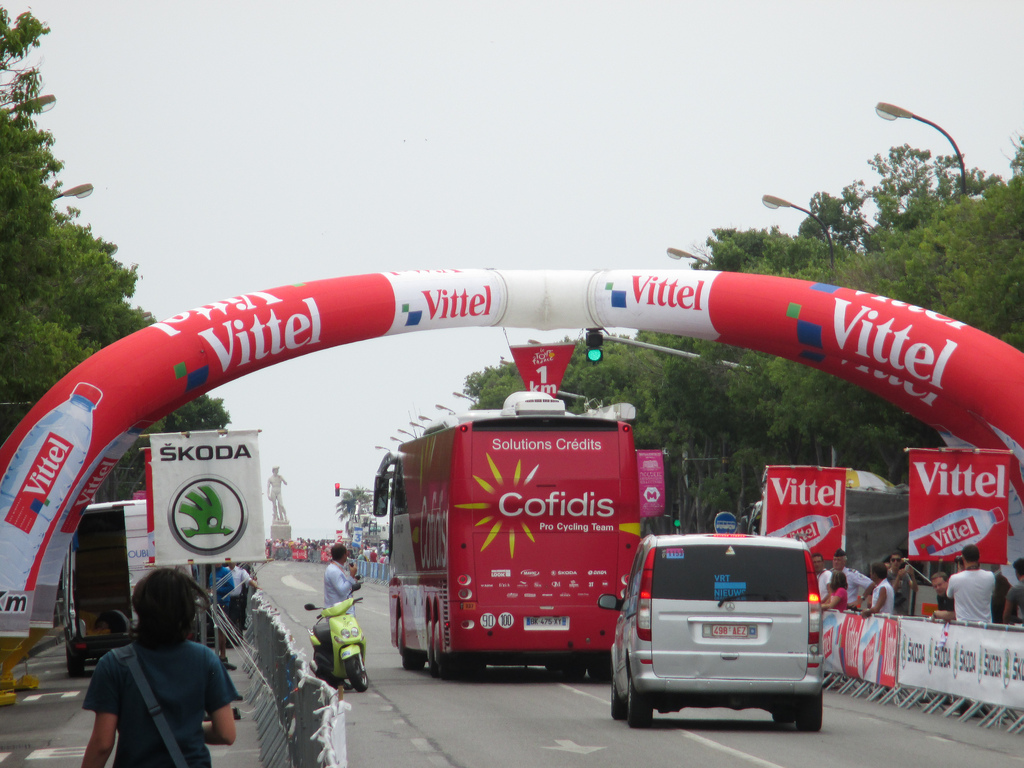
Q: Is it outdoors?
A: Yes, it is outdoors.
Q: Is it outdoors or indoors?
A: It is outdoors.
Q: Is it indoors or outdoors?
A: It is outdoors.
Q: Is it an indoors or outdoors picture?
A: It is outdoors.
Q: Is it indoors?
A: No, it is outdoors.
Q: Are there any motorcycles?
A: Yes, there is a motorcycle.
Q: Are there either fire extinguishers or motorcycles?
A: Yes, there is a motorcycle.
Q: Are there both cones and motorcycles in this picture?
A: No, there is a motorcycle but no cones.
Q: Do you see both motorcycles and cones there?
A: No, there is a motorcycle but no cones.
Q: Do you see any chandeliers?
A: No, there are no chandeliers.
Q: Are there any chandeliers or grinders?
A: No, there are no chandeliers or grinders.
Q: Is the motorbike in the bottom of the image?
A: Yes, the motorbike is in the bottom of the image.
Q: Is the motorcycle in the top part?
A: No, the motorcycle is in the bottom of the image.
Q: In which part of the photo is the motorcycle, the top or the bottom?
A: The motorcycle is in the bottom of the image.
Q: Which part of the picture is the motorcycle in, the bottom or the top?
A: The motorcycle is in the bottom of the image.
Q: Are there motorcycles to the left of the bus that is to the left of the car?
A: Yes, there is a motorcycle to the left of the bus.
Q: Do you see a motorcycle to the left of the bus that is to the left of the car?
A: Yes, there is a motorcycle to the left of the bus.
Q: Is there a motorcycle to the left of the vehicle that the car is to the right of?
A: Yes, there is a motorcycle to the left of the bus.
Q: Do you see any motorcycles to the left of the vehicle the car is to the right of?
A: Yes, there is a motorcycle to the left of the bus.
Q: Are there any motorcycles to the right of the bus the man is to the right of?
A: No, the motorcycle is to the left of the bus.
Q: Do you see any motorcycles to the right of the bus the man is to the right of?
A: No, the motorcycle is to the left of the bus.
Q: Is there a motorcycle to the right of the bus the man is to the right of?
A: No, the motorcycle is to the left of the bus.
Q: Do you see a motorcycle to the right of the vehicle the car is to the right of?
A: No, the motorcycle is to the left of the bus.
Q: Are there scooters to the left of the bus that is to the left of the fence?
A: No, there is a motorcycle to the left of the bus.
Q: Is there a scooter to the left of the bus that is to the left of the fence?
A: No, there is a motorcycle to the left of the bus.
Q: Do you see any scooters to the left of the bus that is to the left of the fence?
A: No, there is a motorcycle to the left of the bus.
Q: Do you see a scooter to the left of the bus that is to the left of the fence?
A: No, there is a motorcycle to the left of the bus.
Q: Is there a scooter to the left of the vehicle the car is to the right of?
A: No, there is a motorcycle to the left of the bus.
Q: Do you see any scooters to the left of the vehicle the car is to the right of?
A: No, there is a motorcycle to the left of the bus.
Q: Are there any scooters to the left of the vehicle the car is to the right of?
A: No, there is a motorcycle to the left of the bus.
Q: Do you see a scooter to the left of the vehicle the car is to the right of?
A: No, there is a motorcycle to the left of the bus.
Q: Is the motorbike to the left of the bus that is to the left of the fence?
A: Yes, the motorbike is to the left of the bus.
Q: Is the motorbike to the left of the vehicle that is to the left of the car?
A: Yes, the motorbike is to the left of the bus.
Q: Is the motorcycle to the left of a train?
A: No, the motorcycle is to the left of the bus.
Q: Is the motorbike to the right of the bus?
A: No, the motorbike is to the left of the bus.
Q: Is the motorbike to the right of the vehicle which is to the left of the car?
A: No, the motorbike is to the left of the bus.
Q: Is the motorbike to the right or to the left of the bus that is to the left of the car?
A: The motorbike is to the left of the bus.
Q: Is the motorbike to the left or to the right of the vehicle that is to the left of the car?
A: The motorbike is to the left of the bus.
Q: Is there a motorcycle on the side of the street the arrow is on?
A: Yes, there is a motorcycle on the side of the street.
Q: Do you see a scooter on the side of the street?
A: No, there is a motorcycle on the side of the street.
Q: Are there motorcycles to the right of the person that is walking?
A: Yes, there is a motorcycle to the right of the person.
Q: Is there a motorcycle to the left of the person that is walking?
A: No, the motorcycle is to the right of the person.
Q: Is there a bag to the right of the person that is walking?
A: No, there is a motorcycle to the right of the person.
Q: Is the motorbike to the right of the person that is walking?
A: Yes, the motorbike is to the right of the person.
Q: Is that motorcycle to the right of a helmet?
A: No, the motorcycle is to the right of the person.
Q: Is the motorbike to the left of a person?
A: No, the motorbike is to the right of a person.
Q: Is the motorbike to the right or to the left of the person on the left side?
A: The motorbike is to the right of the person.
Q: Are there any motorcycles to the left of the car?
A: Yes, there is a motorcycle to the left of the car.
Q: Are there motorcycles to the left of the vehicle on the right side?
A: Yes, there is a motorcycle to the left of the car.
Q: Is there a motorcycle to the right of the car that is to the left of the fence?
A: No, the motorcycle is to the left of the car.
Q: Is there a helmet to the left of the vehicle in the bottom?
A: No, there is a motorcycle to the left of the car.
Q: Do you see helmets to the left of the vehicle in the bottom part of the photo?
A: No, there is a motorcycle to the left of the car.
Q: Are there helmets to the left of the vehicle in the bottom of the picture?
A: No, there is a motorcycle to the left of the car.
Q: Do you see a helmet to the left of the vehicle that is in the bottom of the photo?
A: No, there is a motorcycle to the left of the car.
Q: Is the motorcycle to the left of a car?
A: Yes, the motorcycle is to the left of a car.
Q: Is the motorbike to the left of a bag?
A: No, the motorbike is to the left of a car.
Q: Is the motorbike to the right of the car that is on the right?
A: No, the motorbike is to the left of the car.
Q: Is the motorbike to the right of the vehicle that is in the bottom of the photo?
A: No, the motorbike is to the left of the car.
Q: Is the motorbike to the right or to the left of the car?
A: The motorbike is to the left of the car.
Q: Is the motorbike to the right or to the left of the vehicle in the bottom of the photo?
A: The motorbike is to the left of the car.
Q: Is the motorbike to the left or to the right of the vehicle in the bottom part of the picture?
A: The motorbike is to the left of the car.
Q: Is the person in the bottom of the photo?
A: Yes, the person is in the bottom of the image.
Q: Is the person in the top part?
A: No, the person is in the bottom of the image.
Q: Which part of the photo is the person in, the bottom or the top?
A: The person is in the bottom of the image.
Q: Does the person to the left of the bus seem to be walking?
A: Yes, the person is walking.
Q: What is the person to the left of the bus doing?
A: The person is walking.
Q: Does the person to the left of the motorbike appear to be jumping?
A: No, the person is walking.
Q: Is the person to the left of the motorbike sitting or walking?
A: The person is walking.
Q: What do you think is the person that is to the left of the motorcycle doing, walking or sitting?
A: The person is walking.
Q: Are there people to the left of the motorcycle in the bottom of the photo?
A: Yes, there is a person to the left of the motorcycle.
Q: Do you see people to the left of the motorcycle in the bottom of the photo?
A: Yes, there is a person to the left of the motorcycle.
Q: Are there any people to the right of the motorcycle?
A: No, the person is to the left of the motorcycle.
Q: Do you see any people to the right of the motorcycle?
A: No, the person is to the left of the motorcycle.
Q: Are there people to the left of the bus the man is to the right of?
A: Yes, there is a person to the left of the bus.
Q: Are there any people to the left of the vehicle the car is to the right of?
A: Yes, there is a person to the left of the bus.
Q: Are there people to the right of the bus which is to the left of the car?
A: No, the person is to the left of the bus.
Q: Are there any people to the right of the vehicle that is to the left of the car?
A: No, the person is to the left of the bus.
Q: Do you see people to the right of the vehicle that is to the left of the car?
A: No, the person is to the left of the bus.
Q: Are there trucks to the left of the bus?
A: No, there is a person to the left of the bus.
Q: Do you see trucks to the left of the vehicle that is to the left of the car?
A: No, there is a person to the left of the bus.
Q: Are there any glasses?
A: No, there are no glasses.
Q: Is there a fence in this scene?
A: Yes, there is a fence.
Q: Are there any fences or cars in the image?
A: Yes, there is a fence.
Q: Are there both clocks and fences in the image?
A: No, there is a fence but no clocks.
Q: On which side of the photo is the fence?
A: The fence is on the right of the image.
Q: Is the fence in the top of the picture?
A: No, the fence is in the bottom of the image.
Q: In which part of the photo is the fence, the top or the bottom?
A: The fence is in the bottom of the image.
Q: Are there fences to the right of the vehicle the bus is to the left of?
A: Yes, there is a fence to the right of the car.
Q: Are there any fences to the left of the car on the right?
A: No, the fence is to the right of the car.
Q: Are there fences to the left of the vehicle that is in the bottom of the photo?
A: No, the fence is to the right of the car.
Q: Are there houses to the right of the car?
A: No, there is a fence to the right of the car.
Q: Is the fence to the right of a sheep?
A: No, the fence is to the right of the car.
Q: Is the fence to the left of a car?
A: No, the fence is to the right of a car.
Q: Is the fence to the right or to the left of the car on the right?
A: The fence is to the right of the car.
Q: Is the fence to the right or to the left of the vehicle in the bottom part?
A: The fence is to the right of the car.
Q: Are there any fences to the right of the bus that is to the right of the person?
A: Yes, there is a fence to the right of the bus.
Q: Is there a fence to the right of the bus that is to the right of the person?
A: Yes, there is a fence to the right of the bus.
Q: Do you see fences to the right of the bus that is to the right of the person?
A: Yes, there is a fence to the right of the bus.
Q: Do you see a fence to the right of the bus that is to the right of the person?
A: Yes, there is a fence to the right of the bus.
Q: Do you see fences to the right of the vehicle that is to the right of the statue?
A: Yes, there is a fence to the right of the bus.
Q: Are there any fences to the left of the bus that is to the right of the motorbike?
A: No, the fence is to the right of the bus.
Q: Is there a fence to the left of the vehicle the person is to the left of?
A: No, the fence is to the right of the bus.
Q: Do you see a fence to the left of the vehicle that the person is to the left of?
A: No, the fence is to the right of the bus.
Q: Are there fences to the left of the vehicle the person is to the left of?
A: No, the fence is to the right of the bus.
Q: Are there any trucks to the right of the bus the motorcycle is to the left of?
A: No, there is a fence to the right of the bus.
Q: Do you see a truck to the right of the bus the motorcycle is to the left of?
A: No, there is a fence to the right of the bus.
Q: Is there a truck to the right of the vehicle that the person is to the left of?
A: No, there is a fence to the right of the bus.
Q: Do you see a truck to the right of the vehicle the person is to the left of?
A: No, there is a fence to the right of the bus.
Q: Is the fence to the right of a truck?
A: No, the fence is to the right of a bus.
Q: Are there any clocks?
A: No, there are no clocks.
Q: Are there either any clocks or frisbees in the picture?
A: No, there are no clocks or frisbees.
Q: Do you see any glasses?
A: No, there are no glasses.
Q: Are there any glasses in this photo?
A: No, there are no glasses.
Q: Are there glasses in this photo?
A: No, there are no glasses.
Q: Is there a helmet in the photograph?
A: No, there are no helmets.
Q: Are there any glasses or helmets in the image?
A: No, there are no helmets or glasses.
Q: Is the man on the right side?
A: Yes, the man is on the right of the image.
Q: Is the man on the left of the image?
A: No, the man is on the right of the image.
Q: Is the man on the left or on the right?
A: The man is on the right of the image.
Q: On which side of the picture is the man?
A: The man is on the right of the image.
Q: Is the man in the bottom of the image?
A: Yes, the man is in the bottom of the image.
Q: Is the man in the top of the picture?
A: No, the man is in the bottom of the image.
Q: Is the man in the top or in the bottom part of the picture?
A: The man is in the bottom of the image.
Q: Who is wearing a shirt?
A: The man is wearing a shirt.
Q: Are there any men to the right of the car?
A: Yes, there is a man to the right of the car.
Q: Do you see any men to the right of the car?
A: Yes, there is a man to the right of the car.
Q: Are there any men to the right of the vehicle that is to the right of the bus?
A: Yes, there is a man to the right of the car.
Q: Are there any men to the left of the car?
A: No, the man is to the right of the car.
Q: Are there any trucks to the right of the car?
A: No, there is a man to the right of the car.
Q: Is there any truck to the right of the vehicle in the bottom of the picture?
A: No, there is a man to the right of the car.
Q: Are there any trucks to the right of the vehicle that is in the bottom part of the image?
A: No, there is a man to the right of the car.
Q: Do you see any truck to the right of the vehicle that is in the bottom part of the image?
A: No, there is a man to the right of the car.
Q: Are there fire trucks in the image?
A: No, there are no fire trucks.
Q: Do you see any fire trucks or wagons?
A: No, there are no fire trucks or wagons.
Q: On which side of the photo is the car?
A: The car is on the right of the image.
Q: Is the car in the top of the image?
A: No, the car is in the bottom of the image.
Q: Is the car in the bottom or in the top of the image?
A: The car is in the bottom of the image.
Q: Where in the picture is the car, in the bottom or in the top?
A: The car is in the bottom of the image.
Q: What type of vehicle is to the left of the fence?
A: The vehicle is a car.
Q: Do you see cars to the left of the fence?
A: Yes, there is a car to the left of the fence.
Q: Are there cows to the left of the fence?
A: No, there is a car to the left of the fence.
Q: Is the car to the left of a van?
A: No, the car is to the left of a fence.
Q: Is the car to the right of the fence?
A: No, the car is to the left of the fence.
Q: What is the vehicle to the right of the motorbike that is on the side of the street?
A: The vehicle is a car.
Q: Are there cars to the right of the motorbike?
A: Yes, there is a car to the right of the motorbike.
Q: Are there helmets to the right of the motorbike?
A: No, there is a car to the right of the motorbike.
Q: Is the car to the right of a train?
A: No, the car is to the right of the motorbike.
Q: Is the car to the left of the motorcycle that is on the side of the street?
A: No, the car is to the right of the motorcycle.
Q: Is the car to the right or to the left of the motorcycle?
A: The car is to the right of the motorcycle.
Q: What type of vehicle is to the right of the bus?
A: The vehicle is a car.